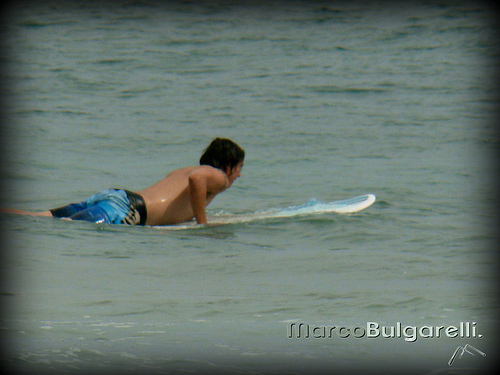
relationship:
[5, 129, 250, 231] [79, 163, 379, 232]
man on top of board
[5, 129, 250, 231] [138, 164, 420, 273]
man laying on surfboard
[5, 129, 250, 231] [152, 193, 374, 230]
man on surfboard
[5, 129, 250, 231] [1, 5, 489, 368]
man paddling out of sea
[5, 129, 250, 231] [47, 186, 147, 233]
man wearing short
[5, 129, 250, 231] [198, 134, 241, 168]
man has hair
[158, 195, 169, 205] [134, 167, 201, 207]
light reflecting on man`s back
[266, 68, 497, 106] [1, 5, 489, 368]
wave in sea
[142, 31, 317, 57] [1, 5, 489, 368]
wave in sea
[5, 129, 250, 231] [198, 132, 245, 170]
man has hair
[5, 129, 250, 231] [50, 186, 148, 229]
man has shorts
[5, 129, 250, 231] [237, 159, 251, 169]
man has eyebrow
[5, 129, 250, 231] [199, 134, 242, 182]
man has head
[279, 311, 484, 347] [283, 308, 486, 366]
photographers on watermark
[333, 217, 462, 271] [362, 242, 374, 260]
ocean seen part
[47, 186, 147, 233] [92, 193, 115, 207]
short seen part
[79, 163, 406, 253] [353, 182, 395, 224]
board has tip